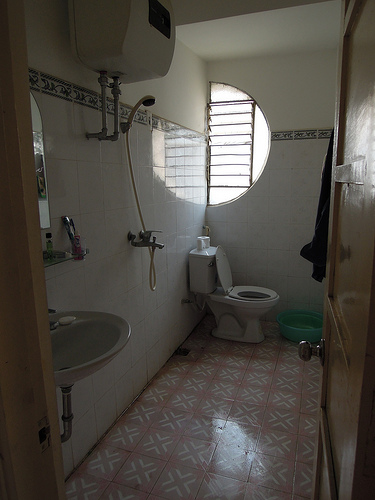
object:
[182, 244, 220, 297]
cistern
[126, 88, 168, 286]
water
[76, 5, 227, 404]
shower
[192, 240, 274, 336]
tank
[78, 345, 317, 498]
bathroom floor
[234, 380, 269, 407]
x pattern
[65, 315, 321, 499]
tiled floor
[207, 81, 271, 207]
window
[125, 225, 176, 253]
faucet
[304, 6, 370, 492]
door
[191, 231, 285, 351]
toilet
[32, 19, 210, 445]
bathroom wall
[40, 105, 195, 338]
tiles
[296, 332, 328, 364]
door knob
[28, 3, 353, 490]
bathroom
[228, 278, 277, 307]
seat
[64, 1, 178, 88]
bathroom fan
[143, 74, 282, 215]
reflection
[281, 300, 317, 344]
bowl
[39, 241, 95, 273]
shelf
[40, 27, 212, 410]
wall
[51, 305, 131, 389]
sink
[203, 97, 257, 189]
rack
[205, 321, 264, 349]
base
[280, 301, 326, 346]
tub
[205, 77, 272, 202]
circle.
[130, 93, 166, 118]
head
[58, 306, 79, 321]
soap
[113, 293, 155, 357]
wall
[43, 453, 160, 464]
pink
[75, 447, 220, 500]
flooring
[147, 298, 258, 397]
standard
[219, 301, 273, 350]
base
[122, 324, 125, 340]
tab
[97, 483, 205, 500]
american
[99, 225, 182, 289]
shower